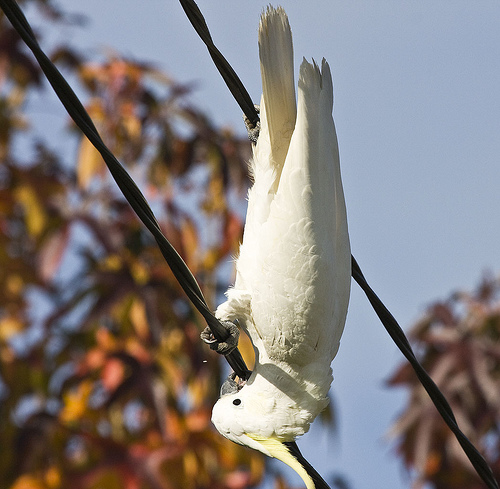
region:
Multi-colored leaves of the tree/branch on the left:
[13, 246, 190, 480]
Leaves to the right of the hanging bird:
[383, 275, 495, 477]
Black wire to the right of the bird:
[356, 280, 431, 339]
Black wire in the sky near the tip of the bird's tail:
[185, 8, 250, 98]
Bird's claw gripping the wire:
[196, 316, 241, 358]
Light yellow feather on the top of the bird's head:
[253, 431, 315, 487]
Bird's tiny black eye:
[225, 393, 247, 413]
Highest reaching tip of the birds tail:
[254, 3, 300, 68]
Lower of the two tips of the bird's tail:
[296, 56, 337, 109]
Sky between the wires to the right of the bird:
[348, 327, 379, 470]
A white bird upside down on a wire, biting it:
[183, 3, 374, 488]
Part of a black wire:
[1, 1, 181, 324]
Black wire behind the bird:
[353, 257, 498, 487]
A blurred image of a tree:
[385, 273, 498, 488]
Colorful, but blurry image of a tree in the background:
[0, 0, 234, 487]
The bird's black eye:
[224, 390, 255, 413]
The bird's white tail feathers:
[249, 2, 346, 195]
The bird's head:
[213, 363, 342, 486]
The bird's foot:
[196, 315, 241, 357]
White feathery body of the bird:
[236, 210, 352, 323]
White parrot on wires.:
[104, 27, 455, 484]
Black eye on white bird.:
[196, 374, 251, 421]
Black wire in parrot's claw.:
[80, 100, 392, 487]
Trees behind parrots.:
[365, 258, 497, 470]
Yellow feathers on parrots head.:
[207, 430, 302, 482]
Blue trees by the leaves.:
[43, 40, 375, 232]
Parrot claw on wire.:
[199, 318, 249, 365]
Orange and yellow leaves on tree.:
[42, 201, 201, 403]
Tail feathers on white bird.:
[244, 21, 396, 187]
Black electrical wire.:
[357, 253, 457, 475]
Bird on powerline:
[202, 14, 352, 486]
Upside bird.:
[168, 212, 333, 455]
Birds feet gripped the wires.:
[186, 311, 260, 374]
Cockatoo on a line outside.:
[150, 255, 330, 481]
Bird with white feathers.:
[180, 243, 392, 473]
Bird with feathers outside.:
[178, 236, 296, 467]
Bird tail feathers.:
[223, 17, 423, 243]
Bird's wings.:
[206, 7, 411, 322]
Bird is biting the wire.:
[185, 350, 285, 430]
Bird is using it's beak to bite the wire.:
[162, 293, 340, 455]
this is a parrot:
[169, 56, 366, 448]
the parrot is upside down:
[202, 20, 352, 467]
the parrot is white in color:
[189, 23, 360, 443]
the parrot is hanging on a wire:
[6, 1, 231, 200]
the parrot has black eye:
[228, 397, 246, 406]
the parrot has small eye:
[230, 397, 242, 404]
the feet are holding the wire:
[196, 318, 242, 349]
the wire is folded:
[1, 16, 196, 275]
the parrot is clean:
[190, 5, 347, 481]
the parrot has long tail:
[245, 2, 307, 62]